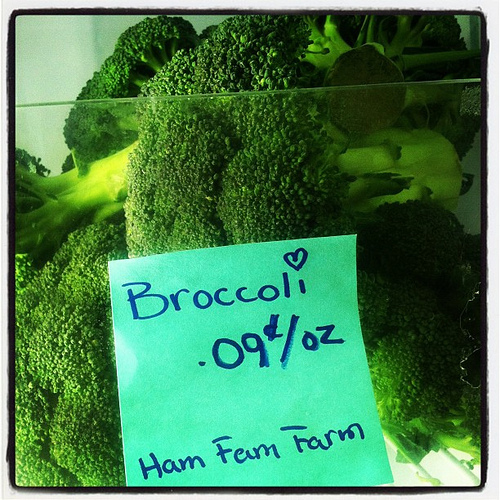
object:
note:
[106, 231, 392, 489]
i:
[298, 278, 307, 294]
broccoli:
[13, 15, 483, 487]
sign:
[263, 314, 284, 342]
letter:
[105, 233, 394, 487]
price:
[197, 310, 346, 370]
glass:
[185, 87, 306, 144]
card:
[106, 234, 394, 486]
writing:
[263, 313, 284, 342]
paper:
[108, 233, 398, 487]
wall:
[11, 13, 146, 177]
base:
[322, 45, 409, 135]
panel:
[8, 97, 483, 286]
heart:
[282, 247, 308, 272]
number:
[241, 332, 270, 368]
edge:
[32, 98, 132, 133]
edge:
[15, 398, 124, 493]